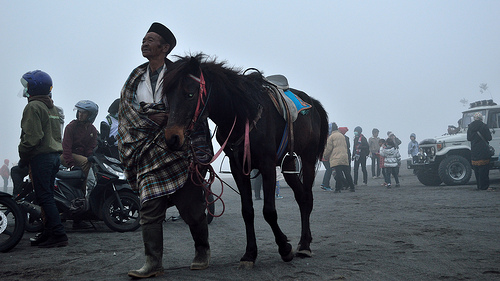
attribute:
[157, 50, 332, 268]
horse — black, good looking, brown, small, brow, led, dark, walking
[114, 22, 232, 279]
man — wrapped, walking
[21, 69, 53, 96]
helmet — protective, motorcycle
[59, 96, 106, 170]
man — sitting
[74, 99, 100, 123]
helmet — motorcycle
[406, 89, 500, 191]
truck — parked, white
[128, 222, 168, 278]
boot — black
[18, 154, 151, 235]
motorcycle — parked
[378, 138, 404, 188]
person — standing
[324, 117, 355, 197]
person — standing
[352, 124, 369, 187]
person — standing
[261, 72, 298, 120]
saddle — leather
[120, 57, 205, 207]
blanket — plaid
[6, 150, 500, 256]
beach — sandy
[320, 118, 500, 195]
group — people, wearing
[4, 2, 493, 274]
sky — gray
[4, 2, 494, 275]
day — misty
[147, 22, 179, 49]
hat — black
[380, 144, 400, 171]
coat — white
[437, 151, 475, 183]
tire — black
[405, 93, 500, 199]
jeep — white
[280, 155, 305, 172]
strap — silver